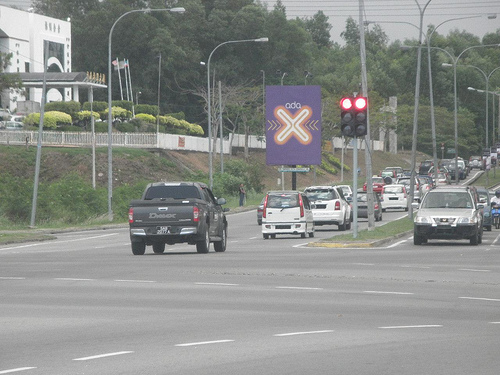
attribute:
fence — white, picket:
[1, 127, 386, 157]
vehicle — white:
[261, 190, 313, 240]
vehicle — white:
[303, 180, 349, 232]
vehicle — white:
[381, 181, 410, 208]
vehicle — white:
[335, 179, 356, 204]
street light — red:
[340, 96, 375, 121]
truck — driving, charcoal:
[125, 178, 230, 256]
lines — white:
[0, 275, 498, 303]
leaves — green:
[130, 22, 195, 64]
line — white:
[0, 271, 500, 303]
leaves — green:
[277, 35, 329, 74]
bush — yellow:
[37, 108, 78, 128]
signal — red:
[342, 98, 367, 110]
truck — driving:
[121, 174, 235, 261]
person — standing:
[234, 178, 249, 209]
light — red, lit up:
[319, 104, 399, 166]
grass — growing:
[64, 194, 84, 214]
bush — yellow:
[33, 111, 75, 128]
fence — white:
[0, 125, 387, 160]